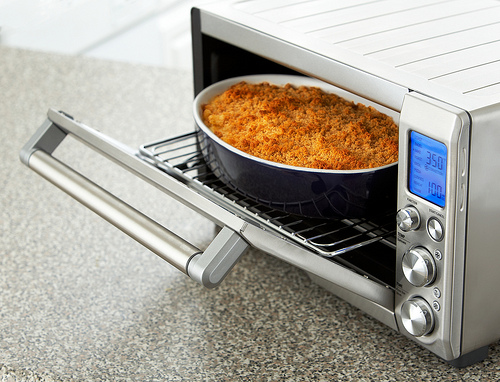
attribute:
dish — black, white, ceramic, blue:
[189, 75, 402, 212]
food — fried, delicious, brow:
[236, 102, 364, 154]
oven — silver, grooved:
[46, 2, 499, 368]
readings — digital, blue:
[406, 126, 447, 206]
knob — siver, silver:
[395, 209, 414, 233]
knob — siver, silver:
[397, 247, 433, 288]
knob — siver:
[399, 298, 432, 336]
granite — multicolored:
[18, 285, 322, 377]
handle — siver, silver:
[29, 155, 202, 280]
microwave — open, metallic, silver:
[49, 2, 499, 367]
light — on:
[402, 125, 448, 209]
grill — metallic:
[152, 139, 203, 177]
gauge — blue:
[401, 129, 451, 206]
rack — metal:
[164, 142, 216, 180]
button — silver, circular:
[424, 218, 443, 244]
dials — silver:
[393, 208, 437, 342]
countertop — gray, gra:
[20, 264, 333, 373]